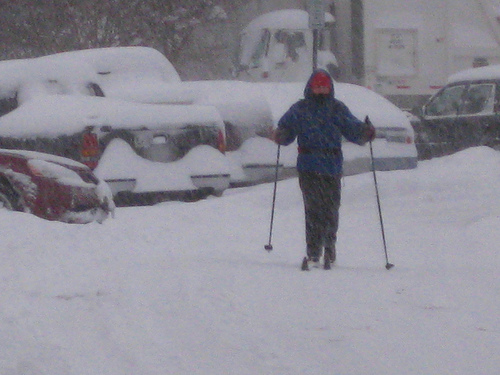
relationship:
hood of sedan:
[4, 142, 104, 172] [1, 141, 145, 234]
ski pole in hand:
[361, 142, 411, 282] [342, 111, 399, 150]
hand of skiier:
[342, 111, 399, 150] [287, 34, 396, 261]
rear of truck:
[59, 102, 184, 169] [34, 83, 255, 184]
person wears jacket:
[271, 68, 376, 271] [273, 98, 363, 174]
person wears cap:
[271, 68, 376, 271] [310, 71, 331, 87]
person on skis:
[253, 55, 402, 275] [264, 194, 414, 341]